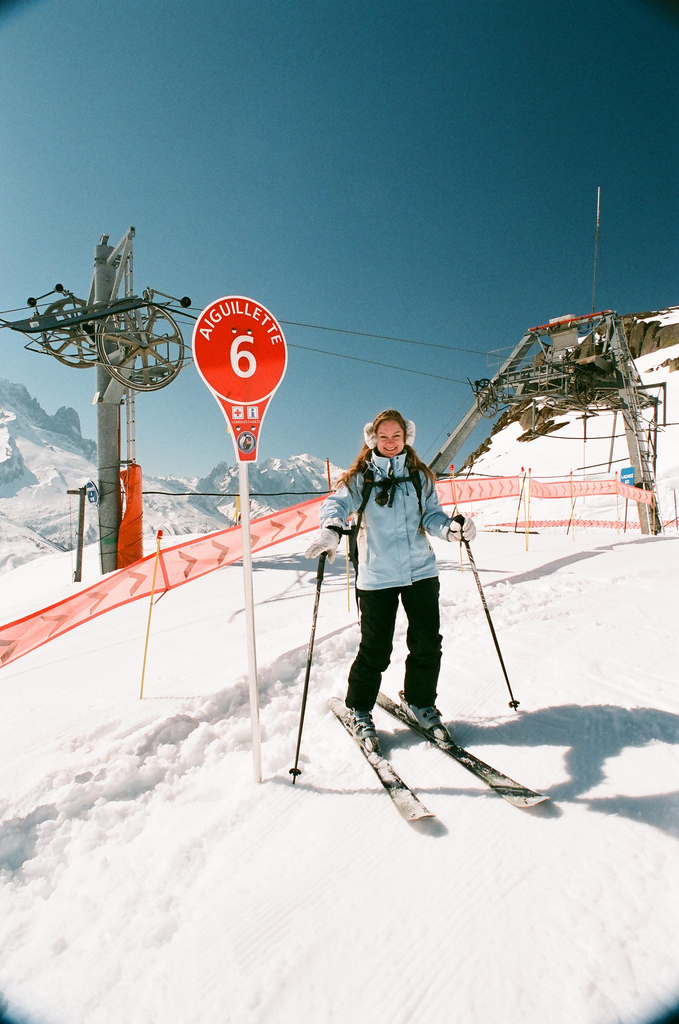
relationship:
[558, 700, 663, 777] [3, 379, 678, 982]
shadow on snow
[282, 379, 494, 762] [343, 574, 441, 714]
girl wearing pants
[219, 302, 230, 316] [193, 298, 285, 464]
letter on sign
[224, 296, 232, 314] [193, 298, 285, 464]
letter on sign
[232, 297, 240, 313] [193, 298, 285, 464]
letter on sign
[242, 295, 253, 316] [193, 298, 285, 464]
letter on sign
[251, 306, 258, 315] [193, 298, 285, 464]
letter on sign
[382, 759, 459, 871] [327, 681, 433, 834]
snow on ski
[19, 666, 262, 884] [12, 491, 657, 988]
track in snow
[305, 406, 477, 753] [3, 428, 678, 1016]
girl on snow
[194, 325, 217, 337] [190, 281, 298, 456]
letter on sign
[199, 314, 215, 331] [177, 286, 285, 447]
letter on sign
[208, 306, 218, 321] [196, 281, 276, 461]
letter on sign